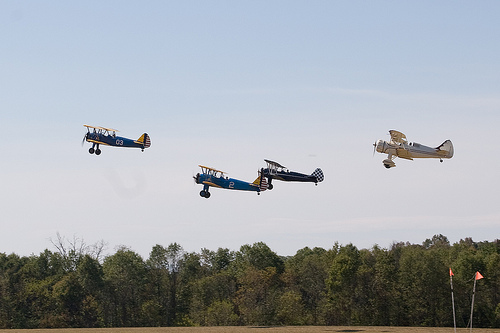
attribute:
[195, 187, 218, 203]
tire — black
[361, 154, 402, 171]
tire — black